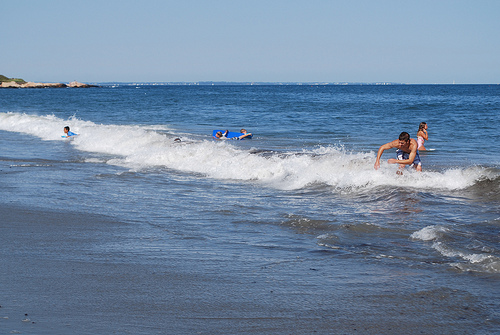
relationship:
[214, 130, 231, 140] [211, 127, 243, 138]
boy on surfboard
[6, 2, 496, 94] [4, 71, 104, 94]
sky over land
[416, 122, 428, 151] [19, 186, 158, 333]
girl facing away from shore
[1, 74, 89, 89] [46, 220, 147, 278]
sand on shore line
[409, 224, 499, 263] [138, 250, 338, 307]
tiny wave coming to shore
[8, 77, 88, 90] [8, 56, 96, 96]
rock in distance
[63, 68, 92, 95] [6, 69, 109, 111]
houses on rock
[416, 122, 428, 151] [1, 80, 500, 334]
girl in beach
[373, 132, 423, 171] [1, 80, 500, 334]
boy in beach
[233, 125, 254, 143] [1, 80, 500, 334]
people in beach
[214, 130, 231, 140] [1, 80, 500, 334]
boy in beach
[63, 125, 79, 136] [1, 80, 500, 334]
boy in beach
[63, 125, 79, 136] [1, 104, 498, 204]
boy in wave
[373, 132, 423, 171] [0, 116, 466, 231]
boy bent over wave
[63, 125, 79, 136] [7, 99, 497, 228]
boy riding wave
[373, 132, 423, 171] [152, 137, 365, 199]
boy in wave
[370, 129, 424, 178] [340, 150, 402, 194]
boy in waves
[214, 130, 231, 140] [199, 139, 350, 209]
boy in waves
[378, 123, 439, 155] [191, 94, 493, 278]
girl in ocean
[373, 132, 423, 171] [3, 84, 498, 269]
boy in ocean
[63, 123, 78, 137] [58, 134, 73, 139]
boy on surfboard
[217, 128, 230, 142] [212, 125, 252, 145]
boy on surfboard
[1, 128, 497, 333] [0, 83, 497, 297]
beach by ocean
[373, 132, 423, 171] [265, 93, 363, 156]
boy in water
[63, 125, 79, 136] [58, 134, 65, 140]
boy on surfboard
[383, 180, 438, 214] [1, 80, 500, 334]
reflection on beach